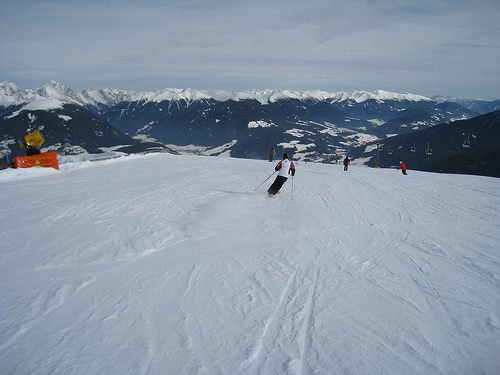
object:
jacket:
[276, 159, 298, 177]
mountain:
[180, 85, 429, 167]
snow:
[210, 187, 376, 311]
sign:
[16, 151, 63, 171]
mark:
[100, 191, 210, 271]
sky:
[0, 0, 499, 99]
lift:
[386, 136, 398, 154]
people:
[341, 155, 351, 175]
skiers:
[393, 159, 414, 176]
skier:
[254, 152, 297, 196]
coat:
[396, 163, 408, 171]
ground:
[85, 185, 285, 276]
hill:
[0, 96, 499, 374]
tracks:
[44, 182, 163, 341]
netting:
[14, 152, 61, 171]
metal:
[410, 135, 463, 147]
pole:
[253, 167, 276, 192]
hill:
[0, 149, 499, 372]